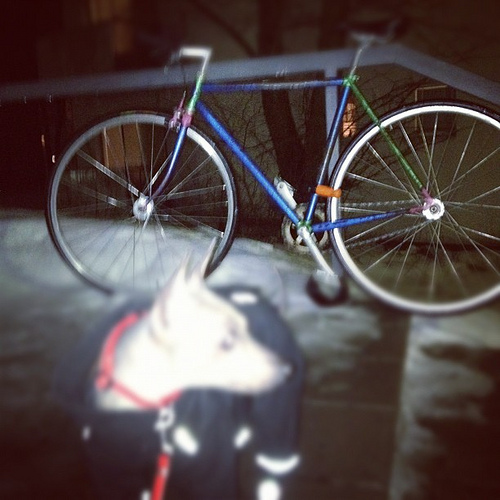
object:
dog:
[59, 236, 304, 499]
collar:
[93, 311, 184, 410]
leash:
[151, 409, 176, 500]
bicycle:
[44, 13, 500, 319]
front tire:
[44, 106, 239, 297]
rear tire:
[324, 98, 500, 317]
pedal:
[271, 173, 296, 198]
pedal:
[309, 269, 343, 300]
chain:
[279, 197, 445, 257]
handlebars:
[166, 45, 212, 66]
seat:
[338, 14, 409, 47]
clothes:
[52, 282, 300, 500]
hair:
[95, 237, 295, 414]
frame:
[142, 43, 434, 236]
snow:
[0, 197, 384, 387]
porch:
[2, 295, 412, 499]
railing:
[1, 41, 500, 282]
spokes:
[55, 123, 228, 283]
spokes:
[338, 112, 499, 303]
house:
[22, 1, 500, 247]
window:
[102, 118, 145, 167]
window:
[108, 21, 133, 53]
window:
[88, 1, 128, 23]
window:
[341, 102, 357, 136]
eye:
[219, 329, 238, 352]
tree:
[186, 1, 352, 248]